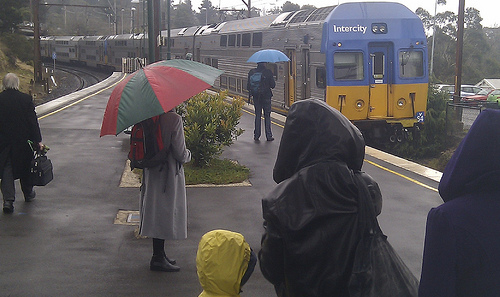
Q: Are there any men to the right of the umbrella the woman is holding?
A: Yes, there is a man to the right of the umbrella.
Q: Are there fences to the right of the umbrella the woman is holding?
A: No, there is a man to the right of the umbrella.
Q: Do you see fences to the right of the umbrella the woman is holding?
A: No, there is a man to the right of the umbrella.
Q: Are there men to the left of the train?
A: Yes, there is a man to the left of the train.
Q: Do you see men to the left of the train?
A: Yes, there is a man to the left of the train.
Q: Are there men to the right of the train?
A: No, the man is to the left of the train.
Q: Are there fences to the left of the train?
A: No, there is a man to the left of the train.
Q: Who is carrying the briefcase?
A: The man is carrying the briefcase.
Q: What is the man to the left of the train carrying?
A: The man is carrying a briefcase.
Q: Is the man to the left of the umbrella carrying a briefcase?
A: Yes, the man is carrying a briefcase.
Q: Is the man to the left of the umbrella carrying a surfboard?
A: No, the man is carrying a briefcase.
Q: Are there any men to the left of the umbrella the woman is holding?
A: Yes, there is a man to the left of the umbrella.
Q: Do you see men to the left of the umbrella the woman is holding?
A: Yes, there is a man to the left of the umbrella.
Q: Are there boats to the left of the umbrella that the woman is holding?
A: No, there is a man to the left of the umbrella.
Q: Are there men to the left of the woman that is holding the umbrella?
A: Yes, there is a man to the left of the woman.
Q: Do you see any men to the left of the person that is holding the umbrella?
A: Yes, there is a man to the left of the woman.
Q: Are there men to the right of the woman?
A: No, the man is to the left of the woman.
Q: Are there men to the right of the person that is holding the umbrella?
A: No, the man is to the left of the woman.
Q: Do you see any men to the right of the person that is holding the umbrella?
A: No, the man is to the left of the woman.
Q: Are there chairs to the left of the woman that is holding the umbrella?
A: No, there is a man to the left of the woman.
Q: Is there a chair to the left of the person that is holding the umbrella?
A: No, there is a man to the left of the woman.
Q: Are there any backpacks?
A: Yes, there is a backpack.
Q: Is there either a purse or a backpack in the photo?
A: Yes, there is a backpack.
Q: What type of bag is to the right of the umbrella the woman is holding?
A: The bag is a backpack.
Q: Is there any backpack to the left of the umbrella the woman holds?
A: No, the backpack is to the right of the umbrella.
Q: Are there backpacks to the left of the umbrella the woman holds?
A: No, the backpack is to the right of the umbrella.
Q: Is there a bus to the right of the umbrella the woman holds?
A: No, there is a backpack to the right of the umbrella.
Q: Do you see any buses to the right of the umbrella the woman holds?
A: No, there is a backpack to the right of the umbrella.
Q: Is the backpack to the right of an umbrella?
A: Yes, the backpack is to the right of an umbrella.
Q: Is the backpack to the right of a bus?
A: No, the backpack is to the right of an umbrella.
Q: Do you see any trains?
A: Yes, there is a train.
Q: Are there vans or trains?
A: Yes, there is a train.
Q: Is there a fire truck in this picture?
A: No, there are no fire trucks.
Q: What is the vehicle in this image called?
A: The vehicle is a train.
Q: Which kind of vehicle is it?
A: The vehicle is a train.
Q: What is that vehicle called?
A: This is a train.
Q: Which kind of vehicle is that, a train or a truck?
A: This is a train.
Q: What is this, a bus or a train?
A: This is a train.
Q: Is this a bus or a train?
A: This is a train.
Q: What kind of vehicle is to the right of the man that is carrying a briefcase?
A: The vehicle is a train.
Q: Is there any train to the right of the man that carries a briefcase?
A: Yes, there is a train to the right of the man.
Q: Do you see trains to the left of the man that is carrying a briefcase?
A: No, the train is to the right of the man.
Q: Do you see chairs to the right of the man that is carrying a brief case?
A: No, there is a train to the right of the man.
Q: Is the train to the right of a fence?
A: No, the train is to the right of the man.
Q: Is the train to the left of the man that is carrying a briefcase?
A: No, the train is to the right of the man.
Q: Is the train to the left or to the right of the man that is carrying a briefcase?
A: The train is to the right of the man.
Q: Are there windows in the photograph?
A: Yes, there is a window.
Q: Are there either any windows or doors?
A: Yes, there is a window.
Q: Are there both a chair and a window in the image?
A: No, there is a window but no chairs.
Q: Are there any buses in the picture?
A: No, there are no buses.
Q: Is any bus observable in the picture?
A: No, there are no buses.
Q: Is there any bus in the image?
A: No, there are no buses.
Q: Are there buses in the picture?
A: No, there are no buses.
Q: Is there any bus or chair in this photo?
A: No, there are no buses or chairs.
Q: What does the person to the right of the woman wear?
A: The person wears a raincoat.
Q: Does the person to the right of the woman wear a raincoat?
A: Yes, the person wears a raincoat.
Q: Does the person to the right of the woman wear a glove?
A: No, the person wears a raincoat.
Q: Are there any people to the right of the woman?
A: Yes, there is a person to the right of the woman.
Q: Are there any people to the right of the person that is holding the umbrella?
A: Yes, there is a person to the right of the woman.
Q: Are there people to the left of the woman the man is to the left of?
A: No, the person is to the right of the woman.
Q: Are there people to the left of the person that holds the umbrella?
A: No, the person is to the right of the woman.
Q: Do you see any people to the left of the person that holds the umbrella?
A: No, the person is to the right of the woman.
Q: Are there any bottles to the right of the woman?
A: No, there is a person to the right of the woman.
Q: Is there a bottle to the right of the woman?
A: No, there is a person to the right of the woman.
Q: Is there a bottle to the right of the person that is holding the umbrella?
A: No, there is a person to the right of the woman.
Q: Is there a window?
A: Yes, there is a window.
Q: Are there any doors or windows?
A: Yes, there is a window.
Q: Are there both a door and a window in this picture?
A: Yes, there are both a window and a door.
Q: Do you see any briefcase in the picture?
A: Yes, there is a briefcase.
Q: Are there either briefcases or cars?
A: Yes, there is a briefcase.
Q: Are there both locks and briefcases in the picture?
A: No, there is a briefcase but no locks.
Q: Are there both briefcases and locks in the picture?
A: No, there is a briefcase but no locks.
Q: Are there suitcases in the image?
A: No, there are no suitcases.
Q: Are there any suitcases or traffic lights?
A: No, there are no suitcases or traffic lights.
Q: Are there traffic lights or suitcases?
A: No, there are no suitcases or traffic lights.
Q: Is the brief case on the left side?
A: Yes, the brief case is on the left of the image.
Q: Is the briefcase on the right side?
A: No, the briefcase is on the left of the image.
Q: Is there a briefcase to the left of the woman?
A: Yes, there is a briefcase to the left of the woman.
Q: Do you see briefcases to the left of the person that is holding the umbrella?
A: Yes, there is a briefcase to the left of the woman.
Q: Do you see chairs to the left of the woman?
A: No, there is a briefcase to the left of the woman.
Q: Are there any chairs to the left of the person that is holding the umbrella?
A: No, there is a briefcase to the left of the woman.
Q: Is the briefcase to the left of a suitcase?
A: No, the briefcase is to the left of a woman.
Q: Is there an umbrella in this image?
A: Yes, there is an umbrella.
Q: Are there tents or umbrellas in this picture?
A: Yes, there is an umbrella.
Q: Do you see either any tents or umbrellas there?
A: Yes, there is an umbrella.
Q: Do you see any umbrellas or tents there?
A: Yes, there is an umbrella.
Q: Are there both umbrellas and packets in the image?
A: No, there is an umbrella but no packets.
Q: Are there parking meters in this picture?
A: No, there are no parking meters.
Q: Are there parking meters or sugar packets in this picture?
A: No, there are no parking meters or sugar packets.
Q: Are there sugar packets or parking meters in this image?
A: No, there are no parking meters or sugar packets.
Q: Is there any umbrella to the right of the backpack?
A: No, the umbrella is to the left of the backpack.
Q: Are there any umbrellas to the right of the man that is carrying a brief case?
A: Yes, there is an umbrella to the right of the man.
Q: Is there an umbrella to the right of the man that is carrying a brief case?
A: Yes, there is an umbrella to the right of the man.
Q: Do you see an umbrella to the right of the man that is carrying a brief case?
A: Yes, there is an umbrella to the right of the man.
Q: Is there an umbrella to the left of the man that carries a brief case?
A: No, the umbrella is to the right of the man.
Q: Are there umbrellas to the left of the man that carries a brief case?
A: No, the umbrella is to the right of the man.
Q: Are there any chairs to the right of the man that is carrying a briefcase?
A: No, there is an umbrella to the right of the man.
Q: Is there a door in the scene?
A: Yes, there is a door.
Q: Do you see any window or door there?
A: Yes, there is a door.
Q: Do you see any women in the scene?
A: Yes, there is a woman.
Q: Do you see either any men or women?
A: Yes, there is a woman.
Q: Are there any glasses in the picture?
A: No, there are no glasses.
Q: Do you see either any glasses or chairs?
A: No, there are no glasses or chairs.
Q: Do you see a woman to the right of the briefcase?
A: Yes, there is a woman to the right of the briefcase.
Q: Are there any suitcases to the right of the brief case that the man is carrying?
A: No, there is a woman to the right of the briefcase.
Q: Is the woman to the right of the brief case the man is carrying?
A: Yes, the woman is to the right of the brief case.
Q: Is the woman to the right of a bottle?
A: No, the woman is to the right of the brief case.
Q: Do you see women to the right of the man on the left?
A: Yes, there is a woman to the right of the man.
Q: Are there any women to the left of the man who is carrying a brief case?
A: No, the woman is to the right of the man.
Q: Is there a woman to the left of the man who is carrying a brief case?
A: No, the woman is to the right of the man.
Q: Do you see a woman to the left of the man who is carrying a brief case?
A: No, the woman is to the right of the man.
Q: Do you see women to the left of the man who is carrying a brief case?
A: No, the woman is to the right of the man.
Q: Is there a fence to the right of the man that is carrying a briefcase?
A: No, there is a woman to the right of the man.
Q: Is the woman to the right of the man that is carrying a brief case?
A: Yes, the woman is to the right of the man.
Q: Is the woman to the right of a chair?
A: No, the woman is to the right of the man.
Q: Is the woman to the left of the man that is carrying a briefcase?
A: No, the woman is to the right of the man.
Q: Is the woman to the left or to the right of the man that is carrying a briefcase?
A: The woman is to the right of the man.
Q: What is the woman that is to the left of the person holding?
A: The woman is holding the umbrella.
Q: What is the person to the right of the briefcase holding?
A: The woman is holding the umbrella.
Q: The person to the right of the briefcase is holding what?
A: The woman is holding the umbrella.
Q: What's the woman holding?
A: The woman is holding the umbrella.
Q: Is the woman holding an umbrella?
A: Yes, the woman is holding an umbrella.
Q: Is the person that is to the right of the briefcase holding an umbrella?
A: Yes, the woman is holding an umbrella.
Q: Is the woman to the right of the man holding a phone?
A: No, the woman is holding an umbrella.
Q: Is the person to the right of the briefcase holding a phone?
A: No, the woman is holding an umbrella.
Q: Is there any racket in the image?
A: No, there are no rackets.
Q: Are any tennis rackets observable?
A: No, there are no tennis rackets.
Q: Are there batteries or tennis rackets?
A: No, there are no tennis rackets or batteries.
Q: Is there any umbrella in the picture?
A: Yes, there is an umbrella.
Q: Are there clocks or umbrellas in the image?
A: Yes, there is an umbrella.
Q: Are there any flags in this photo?
A: No, there are no flags.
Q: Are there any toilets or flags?
A: No, there are no flags or toilets.